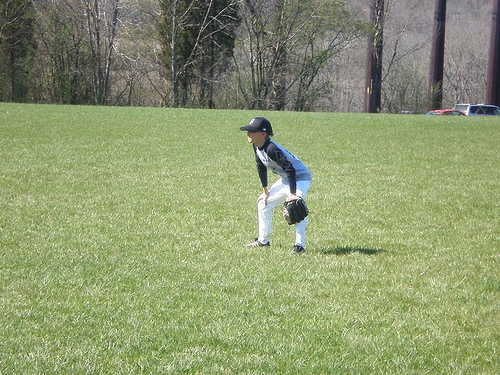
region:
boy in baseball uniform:
[233, 111, 328, 261]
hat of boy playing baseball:
[230, 112, 279, 139]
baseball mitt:
[280, 191, 313, 229]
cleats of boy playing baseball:
[245, 232, 315, 252]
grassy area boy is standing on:
[0, 100, 499, 374]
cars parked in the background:
[417, 96, 499, 113]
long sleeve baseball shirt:
[248, 141, 310, 195]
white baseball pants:
[254, 175, 319, 240]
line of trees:
[1, 1, 499, 103]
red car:
[413, 109, 470, 124]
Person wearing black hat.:
[245, 105, 278, 156]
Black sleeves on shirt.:
[260, 145, 321, 200]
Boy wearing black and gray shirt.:
[253, 139, 314, 208]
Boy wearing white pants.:
[246, 190, 323, 262]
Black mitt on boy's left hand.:
[276, 194, 322, 237]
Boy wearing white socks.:
[249, 230, 298, 270]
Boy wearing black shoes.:
[248, 219, 319, 310]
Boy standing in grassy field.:
[240, 215, 346, 320]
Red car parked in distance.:
[425, 103, 477, 152]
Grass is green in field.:
[48, 127, 220, 334]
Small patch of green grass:
[197, 284, 236, 320]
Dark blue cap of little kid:
[247, 117, 267, 131]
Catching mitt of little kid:
[283, 201, 305, 220]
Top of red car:
[437, 106, 463, 114]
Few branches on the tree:
[196, 22, 220, 59]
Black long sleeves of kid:
[271, 150, 296, 188]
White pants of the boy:
[261, 199, 273, 237]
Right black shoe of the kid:
[246, 240, 266, 250]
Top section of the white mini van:
[462, 102, 497, 115]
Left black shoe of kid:
[292, 245, 309, 260]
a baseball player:
[214, 103, 333, 273]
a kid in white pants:
[221, 107, 322, 269]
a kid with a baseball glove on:
[219, 107, 320, 261]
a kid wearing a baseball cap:
[218, 102, 326, 256]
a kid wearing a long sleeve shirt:
[218, 110, 344, 283]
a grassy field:
[26, 121, 134, 281]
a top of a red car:
[411, 106, 470, 121]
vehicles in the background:
[422, 90, 499, 124]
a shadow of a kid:
[317, 234, 405, 266]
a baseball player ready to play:
[203, 105, 341, 282]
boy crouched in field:
[233, 110, 327, 260]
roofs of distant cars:
[431, 99, 488, 123]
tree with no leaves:
[100, 11, 142, 73]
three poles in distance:
[357, 17, 498, 108]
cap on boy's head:
[237, 112, 278, 142]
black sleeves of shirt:
[270, 145, 299, 189]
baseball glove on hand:
[278, 195, 310, 229]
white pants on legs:
[251, 174, 311, 240]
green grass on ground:
[117, 218, 208, 270]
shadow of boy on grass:
[318, 242, 381, 264]